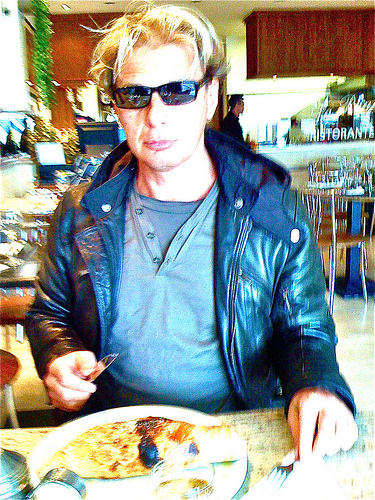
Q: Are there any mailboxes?
A: No, there are no mailboxes.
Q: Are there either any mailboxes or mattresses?
A: No, there are no mailboxes or mattresses.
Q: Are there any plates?
A: Yes, there is a plate.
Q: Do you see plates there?
A: Yes, there is a plate.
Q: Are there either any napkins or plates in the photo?
A: Yes, there is a plate.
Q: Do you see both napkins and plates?
A: No, there is a plate but no napkins.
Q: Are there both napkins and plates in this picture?
A: No, there is a plate but no napkins.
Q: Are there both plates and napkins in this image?
A: No, there is a plate but no napkins.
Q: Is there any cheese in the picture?
A: No, there is no cheese.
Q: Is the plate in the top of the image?
A: No, the plate is in the bottom of the image.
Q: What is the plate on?
A: The plate is on the table.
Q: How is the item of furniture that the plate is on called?
A: The piece of furniture is a table.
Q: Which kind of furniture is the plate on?
A: The plate is on the table.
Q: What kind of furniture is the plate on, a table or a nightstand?
A: The plate is on a table.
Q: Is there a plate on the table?
A: Yes, there is a plate on the table.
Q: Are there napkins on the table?
A: No, there is a plate on the table.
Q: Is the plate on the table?
A: Yes, the plate is on the table.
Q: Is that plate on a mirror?
A: No, the plate is on the table.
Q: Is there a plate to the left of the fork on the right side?
A: Yes, there is a plate to the left of the fork.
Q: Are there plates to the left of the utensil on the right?
A: Yes, there is a plate to the left of the fork.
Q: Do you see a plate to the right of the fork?
A: No, the plate is to the left of the fork.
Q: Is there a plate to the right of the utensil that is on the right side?
A: No, the plate is to the left of the fork.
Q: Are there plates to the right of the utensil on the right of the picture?
A: No, the plate is to the left of the fork.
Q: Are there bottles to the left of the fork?
A: No, there is a plate to the left of the fork.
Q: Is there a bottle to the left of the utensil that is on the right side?
A: No, there is a plate to the left of the fork.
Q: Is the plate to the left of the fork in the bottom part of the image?
A: Yes, the plate is to the left of the fork.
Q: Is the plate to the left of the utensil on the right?
A: Yes, the plate is to the left of the fork.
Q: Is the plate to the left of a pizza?
A: No, the plate is to the left of the fork.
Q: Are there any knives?
A: Yes, there is a knife.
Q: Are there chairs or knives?
A: Yes, there is a knife.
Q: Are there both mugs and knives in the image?
A: No, there is a knife but no mugs.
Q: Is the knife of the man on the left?
A: Yes, the knife is on the left of the image.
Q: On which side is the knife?
A: The knife is on the left of the image.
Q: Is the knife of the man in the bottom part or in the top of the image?
A: The knife is in the bottom of the image.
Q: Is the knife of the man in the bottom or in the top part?
A: The knife is in the bottom of the image.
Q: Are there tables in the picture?
A: Yes, there is a table.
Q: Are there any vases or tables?
A: Yes, there is a table.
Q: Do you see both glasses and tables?
A: Yes, there are both a table and glasses.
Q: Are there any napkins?
A: No, there are no napkins.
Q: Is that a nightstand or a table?
A: That is a table.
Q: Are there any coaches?
A: No, there are no coaches.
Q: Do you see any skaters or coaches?
A: No, there are no coaches or skaters.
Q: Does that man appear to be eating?
A: Yes, the man is eating.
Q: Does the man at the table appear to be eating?
A: Yes, the man is eating.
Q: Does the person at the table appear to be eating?
A: Yes, the man is eating.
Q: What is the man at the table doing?
A: The man is eating.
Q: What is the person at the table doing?
A: The man is eating.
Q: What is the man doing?
A: The man is eating.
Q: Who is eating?
A: The man is eating.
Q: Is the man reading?
A: No, the man is eating.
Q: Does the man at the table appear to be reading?
A: No, the man is eating.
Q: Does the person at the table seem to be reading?
A: No, the man is eating.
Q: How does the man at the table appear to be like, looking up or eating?
A: The man is eating.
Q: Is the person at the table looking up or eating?
A: The man is eating.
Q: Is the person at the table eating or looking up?
A: The man is eating.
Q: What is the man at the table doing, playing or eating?
A: The man is eating.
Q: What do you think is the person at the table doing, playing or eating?
A: The man is eating.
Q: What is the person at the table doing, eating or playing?
A: The man is eating.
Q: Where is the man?
A: The man is at the table.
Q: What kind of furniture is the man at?
A: The man is at the table.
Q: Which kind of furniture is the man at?
A: The man is at the table.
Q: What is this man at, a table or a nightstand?
A: The man is at a table.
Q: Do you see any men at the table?
A: Yes, there is a man at the table.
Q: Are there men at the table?
A: Yes, there is a man at the table.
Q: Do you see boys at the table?
A: No, there is a man at the table.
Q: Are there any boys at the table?
A: No, there is a man at the table.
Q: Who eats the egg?
A: The man eats the egg.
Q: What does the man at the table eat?
A: The man eats an egg.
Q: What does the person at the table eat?
A: The man eats an egg.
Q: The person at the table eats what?
A: The man eats an egg.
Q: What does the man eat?
A: The man eats an egg.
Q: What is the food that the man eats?
A: The food is an egg.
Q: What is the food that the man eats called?
A: The food is an egg.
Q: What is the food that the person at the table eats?
A: The food is an egg.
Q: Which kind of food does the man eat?
A: The man eats an egg.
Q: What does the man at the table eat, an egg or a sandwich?
A: The man eats an egg.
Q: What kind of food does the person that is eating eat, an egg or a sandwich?
A: The man eats an egg.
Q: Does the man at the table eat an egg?
A: Yes, the man eats an egg.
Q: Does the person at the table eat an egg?
A: Yes, the man eats an egg.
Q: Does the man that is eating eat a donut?
A: No, the man eats an egg.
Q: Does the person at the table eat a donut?
A: No, the man eats an egg.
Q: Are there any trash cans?
A: No, there are no trash cans.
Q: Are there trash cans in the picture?
A: No, there are no trash cans.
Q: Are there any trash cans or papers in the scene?
A: No, there are no trash cans or papers.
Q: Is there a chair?
A: Yes, there is a chair.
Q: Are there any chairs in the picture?
A: Yes, there is a chair.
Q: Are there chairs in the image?
A: Yes, there is a chair.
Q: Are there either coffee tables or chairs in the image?
A: Yes, there is a chair.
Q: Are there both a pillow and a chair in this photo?
A: No, there is a chair but no pillows.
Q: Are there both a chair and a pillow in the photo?
A: No, there is a chair but no pillows.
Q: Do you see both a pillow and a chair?
A: No, there is a chair but no pillows.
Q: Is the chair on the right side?
A: Yes, the chair is on the right of the image.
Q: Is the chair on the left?
A: No, the chair is on the right of the image.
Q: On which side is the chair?
A: The chair is on the right of the image.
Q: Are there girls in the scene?
A: No, there are no girls.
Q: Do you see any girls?
A: No, there are no girls.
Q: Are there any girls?
A: No, there are no girls.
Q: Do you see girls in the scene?
A: No, there are no girls.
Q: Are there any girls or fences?
A: No, there are no girls or fences.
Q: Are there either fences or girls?
A: No, there are no girls or fences.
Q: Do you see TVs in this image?
A: No, there are no tvs.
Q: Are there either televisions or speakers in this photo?
A: No, there are no televisions or speakers.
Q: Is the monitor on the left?
A: Yes, the monitor is on the left of the image.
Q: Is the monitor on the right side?
A: No, the monitor is on the left of the image.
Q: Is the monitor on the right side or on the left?
A: The monitor is on the left of the image.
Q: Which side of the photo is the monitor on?
A: The monitor is on the left of the image.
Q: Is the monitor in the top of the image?
A: Yes, the monitor is in the top of the image.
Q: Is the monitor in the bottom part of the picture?
A: No, the monitor is in the top of the image.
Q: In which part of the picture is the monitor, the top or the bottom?
A: The monitor is in the top of the image.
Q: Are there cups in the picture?
A: Yes, there is a cup.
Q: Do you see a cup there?
A: Yes, there is a cup.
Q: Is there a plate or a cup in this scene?
A: Yes, there is a cup.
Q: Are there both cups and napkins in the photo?
A: No, there is a cup but no napkins.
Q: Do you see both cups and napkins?
A: No, there is a cup but no napkins.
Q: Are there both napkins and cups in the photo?
A: No, there is a cup but no napkins.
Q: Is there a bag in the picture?
A: No, there are no bags.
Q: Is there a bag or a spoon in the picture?
A: No, there are no bags or spoons.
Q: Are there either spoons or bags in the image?
A: No, there are no bags or spoons.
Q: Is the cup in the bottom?
A: Yes, the cup is in the bottom of the image.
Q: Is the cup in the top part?
A: No, the cup is in the bottom of the image.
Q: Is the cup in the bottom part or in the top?
A: The cup is in the bottom of the image.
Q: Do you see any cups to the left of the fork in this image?
A: Yes, there is a cup to the left of the fork.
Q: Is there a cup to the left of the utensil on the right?
A: Yes, there is a cup to the left of the fork.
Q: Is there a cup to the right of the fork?
A: No, the cup is to the left of the fork.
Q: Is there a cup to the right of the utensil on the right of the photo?
A: No, the cup is to the left of the fork.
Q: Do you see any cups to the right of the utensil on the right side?
A: No, the cup is to the left of the fork.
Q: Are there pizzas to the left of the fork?
A: No, there is a cup to the left of the fork.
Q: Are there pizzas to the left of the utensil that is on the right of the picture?
A: No, there is a cup to the left of the fork.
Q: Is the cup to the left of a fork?
A: Yes, the cup is to the left of a fork.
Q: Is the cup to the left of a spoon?
A: No, the cup is to the left of a fork.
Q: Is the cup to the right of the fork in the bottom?
A: No, the cup is to the left of the fork.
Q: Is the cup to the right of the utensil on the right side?
A: No, the cup is to the left of the fork.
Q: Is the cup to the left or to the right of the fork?
A: The cup is to the left of the fork.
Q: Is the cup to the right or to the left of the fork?
A: The cup is to the left of the fork.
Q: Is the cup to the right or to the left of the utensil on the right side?
A: The cup is to the left of the fork.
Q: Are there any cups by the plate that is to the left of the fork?
A: Yes, there is a cup by the plate.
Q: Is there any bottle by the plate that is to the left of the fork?
A: No, there is a cup by the plate.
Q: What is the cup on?
A: The cup is on the table.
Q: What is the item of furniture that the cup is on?
A: The piece of furniture is a table.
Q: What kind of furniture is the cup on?
A: The cup is on the table.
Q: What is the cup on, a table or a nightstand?
A: The cup is on a table.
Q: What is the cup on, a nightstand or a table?
A: The cup is on a table.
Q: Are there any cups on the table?
A: Yes, there is a cup on the table.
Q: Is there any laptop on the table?
A: No, there is a cup on the table.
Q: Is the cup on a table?
A: Yes, the cup is on a table.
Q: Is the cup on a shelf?
A: No, the cup is on a table.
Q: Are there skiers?
A: No, there are no skiers.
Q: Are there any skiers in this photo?
A: No, there are no skiers.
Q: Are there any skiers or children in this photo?
A: No, there are no skiers or children.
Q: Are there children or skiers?
A: No, there are no skiers or children.